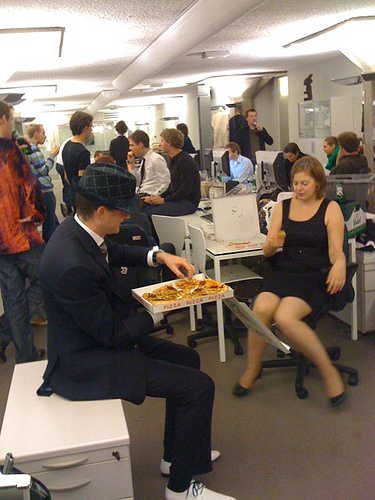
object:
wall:
[140, 69, 275, 141]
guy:
[39, 154, 243, 500]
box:
[129, 270, 290, 353]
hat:
[72, 160, 149, 217]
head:
[74, 159, 140, 235]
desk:
[151, 206, 281, 364]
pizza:
[123, 145, 136, 157]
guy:
[235, 109, 270, 162]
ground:
[270, 421, 344, 497]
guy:
[125, 125, 171, 216]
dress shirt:
[137, 148, 171, 195]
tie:
[137, 160, 147, 183]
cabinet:
[0, 358, 133, 500]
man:
[141, 125, 202, 217]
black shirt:
[155, 151, 201, 205]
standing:
[1, 99, 70, 365]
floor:
[241, 420, 366, 490]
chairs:
[182, 219, 261, 338]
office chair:
[293, 361, 308, 400]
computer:
[204, 149, 231, 176]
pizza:
[144, 276, 222, 306]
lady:
[233, 155, 346, 408]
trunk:
[0, 359, 133, 500]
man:
[271, 141, 326, 197]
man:
[63, 108, 95, 223]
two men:
[127, 125, 203, 232]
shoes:
[161, 448, 220, 478]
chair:
[255, 221, 359, 400]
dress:
[266, 197, 345, 308]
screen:
[252, 145, 284, 185]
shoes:
[161, 480, 232, 499]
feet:
[166, 476, 236, 500]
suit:
[35, 212, 215, 471]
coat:
[234, 126, 276, 157]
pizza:
[268, 223, 293, 256]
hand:
[266, 233, 292, 253]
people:
[0, 91, 44, 364]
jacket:
[34, 212, 159, 409]